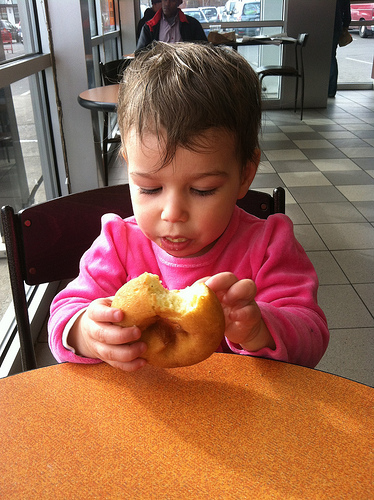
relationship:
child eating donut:
[48, 41, 326, 373] [110, 270, 224, 368]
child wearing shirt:
[48, 41, 326, 373] [48, 213, 331, 368]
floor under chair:
[250, 88, 373, 384] [252, 32, 309, 117]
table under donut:
[0, 350, 373, 499] [110, 270, 224, 368]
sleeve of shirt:
[223, 212, 331, 367] [48, 213, 331, 368]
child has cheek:
[48, 41, 326, 373] [133, 206, 159, 237]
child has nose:
[48, 41, 326, 373] [161, 187, 188, 223]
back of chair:
[296, 32, 308, 75] [252, 32, 309, 117]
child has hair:
[48, 41, 326, 373] [117, 38, 262, 174]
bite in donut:
[148, 273, 210, 318] [110, 270, 224, 368]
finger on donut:
[88, 298, 125, 323] [110, 270, 224, 368]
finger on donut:
[86, 322, 142, 346] [110, 270, 224, 368]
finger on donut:
[95, 342, 150, 362] [110, 270, 224, 368]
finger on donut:
[106, 361, 146, 372] [110, 270, 224, 368]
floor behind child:
[250, 88, 373, 384] [48, 41, 326, 373]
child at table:
[48, 41, 326, 373] [0, 350, 373, 499]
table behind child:
[76, 82, 123, 186] [48, 41, 326, 373]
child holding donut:
[48, 41, 326, 373] [110, 270, 224, 368]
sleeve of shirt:
[49, 211, 124, 364] [48, 213, 331, 368]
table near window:
[76, 82, 123, 186] [1, 1, 63, 364]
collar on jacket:
[147, 9, 164, 29] [135, 9, 208, 56]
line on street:
[345, 56, 374, 68] [336, 32, 374, 83]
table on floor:
[76, 82, 123, 186] [250, 88, 373, 384]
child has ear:
[48, 41, 326, 373] [237, 145, 260, 200]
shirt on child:
[48, 213, 331, 368] [48, 41, 326, 373]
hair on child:
[117, 38, 262, 174] [48, 41, 326, 373]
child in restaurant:
[48, 41, 326, 373] [1, 1, 373, 499]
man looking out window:
[135, 0, 209, 57] [88, 4, 122, 86]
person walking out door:
[330, 0, 354, 96] [336, 1, 373, 90]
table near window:
[207, 37, 298, 70] [178, 1, 283, 95]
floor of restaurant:
[250, 88, 373, 384] [1, 1, 373, 499]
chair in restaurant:
[252, 32, 309, 117] [1, 1, 373, 499]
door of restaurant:
[336, 1, 373, 90] [1, 1, 373, 499]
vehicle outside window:
[219, 1, 261, 35] [178, 1, 283, 95]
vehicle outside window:
[179, 8, 209, 33] [178, 1, 283, 95]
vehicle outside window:
[198, 6, 222, 27] [178, 1, 283, 95]